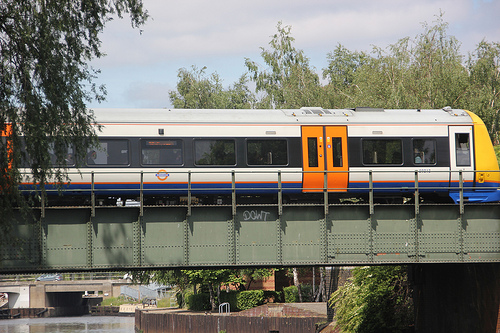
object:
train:
[14, 60, 499, 243]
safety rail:
[0, 170, 500, 217]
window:
[246, 138, 288, 165]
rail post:
[187, 170, 191, 217]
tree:
[167, 10, 499, 107]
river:
[0, 315, 134, 333]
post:
[232, 170, 237, 216]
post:
[415, 170, 420, 215]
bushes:
[177, 290, 283, 311]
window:
[307, 137, 318, 168]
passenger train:
[0, 105, 500, 204]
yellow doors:
[301, 125, 350, 193]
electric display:
[148, 140, 173, 146]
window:
[86, 139, 130, 166]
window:
[455, 132, 472, 166]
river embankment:
[134, 307, 328, 333]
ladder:
[218, 303, 230, 316]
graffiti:
[242, 210, 270, 221]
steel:
[320, 209, 328, 263]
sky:
[152, 2, 242, 55]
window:
[411, 137, 436, 164]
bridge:
[0, 202, 500, 272]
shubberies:
[283, 285, 299, 303]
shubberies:
[236, 289, 264, 310]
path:
[231, 303, 326, 317]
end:
[461, 109, 500, 191]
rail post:
[323, 171, 329, 215]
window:
[141, 139, 183, 166]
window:
[362, 139, 402, 164]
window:
[194, 137, 236, 166]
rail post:
[0, 192, 444, 208]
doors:
[301, 125, 349, 193]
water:
[38, 322, 101, 333]